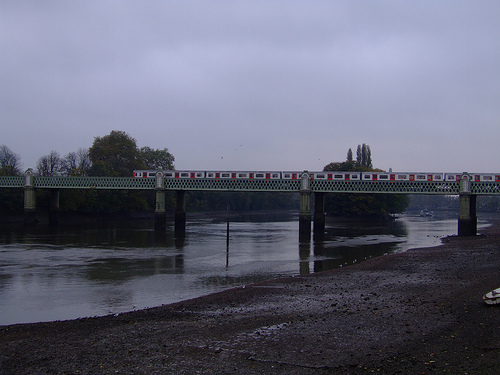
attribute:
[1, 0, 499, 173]
clouds — white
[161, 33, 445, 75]
cloud — white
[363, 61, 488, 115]
sky — blue, white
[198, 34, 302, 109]
clouds — white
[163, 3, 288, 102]
clouds — white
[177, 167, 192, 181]
window — white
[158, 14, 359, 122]
cloud — white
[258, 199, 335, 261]
column — reflection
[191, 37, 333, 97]
clouds — white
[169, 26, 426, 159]
clouds — white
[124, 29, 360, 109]
clouds — white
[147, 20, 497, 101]
clouds — white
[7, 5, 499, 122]
sky — blue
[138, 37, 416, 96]
clouds — white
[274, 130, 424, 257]
trees — island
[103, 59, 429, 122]
clouds — white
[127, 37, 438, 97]
clouds — white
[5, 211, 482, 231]
shore line — sandy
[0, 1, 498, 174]
sky — blue, grey, overcast